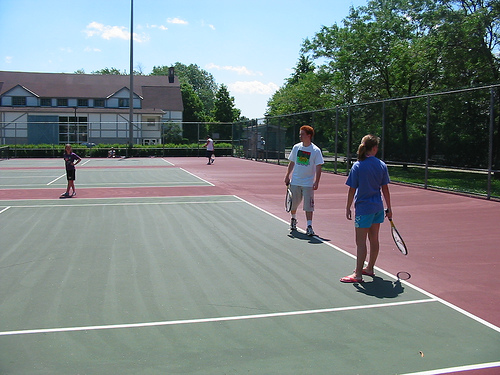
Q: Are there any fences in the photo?
A: Yes, there is a fence.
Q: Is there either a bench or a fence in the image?
A: Yes, there is a fence.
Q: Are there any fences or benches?
A: Yes, there is a fence.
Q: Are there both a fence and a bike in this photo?
A: No, there is a fence but no bikes.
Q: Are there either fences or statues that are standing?
A: Yes, the fence is standing.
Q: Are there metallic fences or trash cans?
A: Yes, there is a metal fence.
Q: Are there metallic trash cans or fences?
A: Yes, there is a metal fence.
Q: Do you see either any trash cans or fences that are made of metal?
A: Yes, the fence is made of metal.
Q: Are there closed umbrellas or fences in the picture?
A: Yes, there is a closed fence.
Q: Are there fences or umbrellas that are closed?
A: Yes, the fence is closed.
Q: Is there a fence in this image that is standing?
A: Yes, there is a fence that is standing.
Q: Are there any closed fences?
A: Yes, there is a closed fence.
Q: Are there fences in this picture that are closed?
A: Yes, there is a fence that is closed.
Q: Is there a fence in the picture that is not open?
A: Yes, there is an closed fence.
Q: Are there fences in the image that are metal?
A: Yes, there is a metal fence.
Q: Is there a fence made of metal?
A: Yes, there is a fence that is made of metal.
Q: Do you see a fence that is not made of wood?
A: Yes, there is a fence that is made of metal.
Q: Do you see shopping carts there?
A: No, there are no shopping carts.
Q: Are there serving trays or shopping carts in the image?
A: No, there are no shopping carts or serving trays.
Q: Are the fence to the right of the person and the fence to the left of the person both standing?
A: Yes, both the fence and the fence are standing.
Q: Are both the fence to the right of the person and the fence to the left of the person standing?
A: Yes, both the fence and the fence are standing.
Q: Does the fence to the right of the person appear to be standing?
A: Yes, the fence is standing.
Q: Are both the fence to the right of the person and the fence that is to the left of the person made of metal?
A: Yes, both the fence and the fence are made of metal.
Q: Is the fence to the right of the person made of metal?
A: Yes, the fence is made of metal.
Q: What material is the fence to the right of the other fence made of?
A: The fence is made of metal.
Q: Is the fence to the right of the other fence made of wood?
A: No, the fence is made of metal.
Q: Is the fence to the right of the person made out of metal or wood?
A: The fence is made of metal.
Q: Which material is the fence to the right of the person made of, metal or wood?
A: The fence is made of metal.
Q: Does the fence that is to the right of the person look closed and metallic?
A: Yes, the fence is closed and metallic.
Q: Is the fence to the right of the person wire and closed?
A: No, the fence is closed but metallic.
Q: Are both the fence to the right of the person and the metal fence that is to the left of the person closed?
A: Yes, both the fence and the fence are closed.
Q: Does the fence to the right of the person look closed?
A: Yes, the fence is closed.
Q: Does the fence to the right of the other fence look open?
A: No, the fence is closed.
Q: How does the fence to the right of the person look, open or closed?
A: The fence is closed.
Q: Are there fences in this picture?
A: Yes, there is a fence.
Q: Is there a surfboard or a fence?
A: Yes, there is a fence.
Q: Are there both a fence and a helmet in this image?
A: No, there is a fence but no helmets.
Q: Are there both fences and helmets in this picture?
A: No, there is a fence but no helmets.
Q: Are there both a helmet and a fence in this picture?
A: No, there is a fence but no helmets.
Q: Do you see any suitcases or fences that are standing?
A: Yes, the fence is standing.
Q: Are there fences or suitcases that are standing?
A: Yes, the fence is standing.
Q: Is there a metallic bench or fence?
A: Yes, there is a metal fence.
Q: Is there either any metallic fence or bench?
A: Yes, there is a metal fence.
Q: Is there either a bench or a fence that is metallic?
A: Yes, the fence is metallic.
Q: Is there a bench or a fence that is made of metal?
A: Yes, the fence is made of metal.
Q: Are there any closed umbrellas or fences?
A: Yes, there is a closed fence.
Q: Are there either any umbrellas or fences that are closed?
A: Yes, the fence is closed.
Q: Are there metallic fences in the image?
A: Yes, there is a metal fence.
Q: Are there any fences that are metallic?
A: Yes, there is a fence that is metallic.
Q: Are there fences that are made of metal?
A: Yes, there is a fence that is made of metal.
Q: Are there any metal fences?
A: Yes, there is a fence that is made of metal.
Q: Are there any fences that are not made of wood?
A: Yes, there is a fence that is made of metal.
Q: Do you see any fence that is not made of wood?
A: Yes, there is a fence that is made of metal.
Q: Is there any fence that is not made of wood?
A: Yes, there is a fence that is made of metal.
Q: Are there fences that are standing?
A: Yes, there is a fence that is standing.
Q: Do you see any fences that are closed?
A: Yes, there is a closed fence.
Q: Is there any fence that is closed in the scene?
A: Yes, there is a closed fence.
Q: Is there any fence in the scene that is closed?
A: Yes, there is a fence that is closed.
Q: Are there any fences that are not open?
A: Yes, there is an closed fence.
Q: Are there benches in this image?
A: No, there are no benches.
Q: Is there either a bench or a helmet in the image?
A: No, there are no benches or helmets.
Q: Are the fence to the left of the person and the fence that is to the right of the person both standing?
A: Yes, both the fence and the fence are standing.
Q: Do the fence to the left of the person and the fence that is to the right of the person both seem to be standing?
A: Yes, both the fence and the fence are standing.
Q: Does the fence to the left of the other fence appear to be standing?
A: Yes, the fence is standing.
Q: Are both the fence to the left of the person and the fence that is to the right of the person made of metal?
A: Yes, both the fence and the fence are made of metal.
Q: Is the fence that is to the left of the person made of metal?
A: Yes, the fence is made of metal.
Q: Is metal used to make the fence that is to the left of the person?
A: Yes, the fence is made of metal.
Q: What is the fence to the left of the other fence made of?
A: The fence is made of metal.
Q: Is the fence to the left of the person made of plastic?
A: No, the fence is made of metal.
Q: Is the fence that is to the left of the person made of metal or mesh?
A: The fence is made of metal.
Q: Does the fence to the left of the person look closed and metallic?
A: Yes, the fence is closed and metallic.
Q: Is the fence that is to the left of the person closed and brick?
A: No, the fence is closed but metallic.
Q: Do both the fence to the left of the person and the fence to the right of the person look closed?
A: Yes, both the fence and the fence are closed.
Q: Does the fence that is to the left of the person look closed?
A: Yes, the fence is closed.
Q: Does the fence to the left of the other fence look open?
A: No, the fence is closed.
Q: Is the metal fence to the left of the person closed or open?
A: The fence is closed.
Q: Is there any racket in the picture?
A: Yes, there is a racket.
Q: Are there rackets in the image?
A: Yes, there is a racket.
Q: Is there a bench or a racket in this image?
A: Yes, there is a racket.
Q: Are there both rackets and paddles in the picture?
A: No, there is a racket but no paddles.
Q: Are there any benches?
A: No, there are no benches.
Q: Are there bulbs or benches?
A: No, there are no benches or bulbs.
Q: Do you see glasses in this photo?
A: No, there are no glasses.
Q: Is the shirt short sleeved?
A: Yes, the shirt is short sleeved.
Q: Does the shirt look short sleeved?
A: Yes, the shirt is short sleeved.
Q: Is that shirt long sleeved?
A: No, the shirt is short sleeved.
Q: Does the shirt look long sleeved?
A: No, the shirt is short sleeved.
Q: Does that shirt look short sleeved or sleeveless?
A: The shirt is short sleeved.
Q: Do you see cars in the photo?
A: No, there are no cars.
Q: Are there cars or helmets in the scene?
A: No, there are no cars or helmets.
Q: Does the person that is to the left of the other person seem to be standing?
A: Yes, the person is standing.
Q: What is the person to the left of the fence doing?
A: The person is standing.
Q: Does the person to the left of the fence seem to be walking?
A: No, the person is standing.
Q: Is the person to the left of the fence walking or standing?
A: The person is standing.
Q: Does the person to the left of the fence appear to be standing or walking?
A: The person is standing.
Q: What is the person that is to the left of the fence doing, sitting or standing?
A: The person is standing.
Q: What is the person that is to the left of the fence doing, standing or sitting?
A: The person is standing.